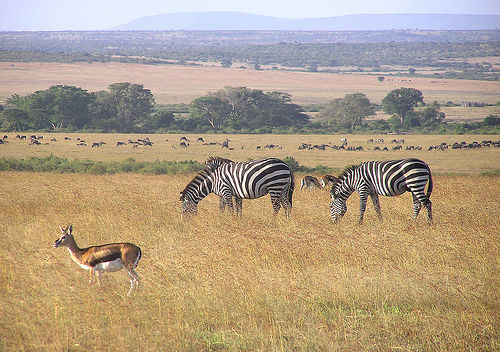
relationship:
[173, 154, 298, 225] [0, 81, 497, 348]
zebra in bush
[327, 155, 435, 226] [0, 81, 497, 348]
zebra in bush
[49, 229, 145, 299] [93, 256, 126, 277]
antelope with belly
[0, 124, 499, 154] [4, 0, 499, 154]
animals in distance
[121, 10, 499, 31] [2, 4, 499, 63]
mountain on horizon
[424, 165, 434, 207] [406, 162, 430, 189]
tail on back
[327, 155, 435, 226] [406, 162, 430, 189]
zebra has back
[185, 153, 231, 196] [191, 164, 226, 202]
mane on neck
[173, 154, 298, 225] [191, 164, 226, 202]
zebra has neck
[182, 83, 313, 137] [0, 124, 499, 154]
tree beyond herd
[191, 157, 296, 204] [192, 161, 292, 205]
stripes on torso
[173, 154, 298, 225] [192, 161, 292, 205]
zebra has torso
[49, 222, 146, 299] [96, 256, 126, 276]
antelope has belly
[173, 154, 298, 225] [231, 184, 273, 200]
zebra has stomach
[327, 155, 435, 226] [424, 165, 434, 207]
zebra has tail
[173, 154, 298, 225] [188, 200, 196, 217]
zebra has jaw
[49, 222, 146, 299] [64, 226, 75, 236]
antelope has ear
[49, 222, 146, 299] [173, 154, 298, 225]
antelope beside zebra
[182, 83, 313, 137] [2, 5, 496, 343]
tree in photo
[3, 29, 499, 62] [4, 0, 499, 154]
savannah in distance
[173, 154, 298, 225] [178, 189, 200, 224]
zebra has head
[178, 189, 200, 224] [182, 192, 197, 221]
head with stripes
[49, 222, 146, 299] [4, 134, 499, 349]
antelope on field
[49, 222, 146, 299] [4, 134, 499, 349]
antelope in field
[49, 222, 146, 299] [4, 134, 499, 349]
antelope standing in field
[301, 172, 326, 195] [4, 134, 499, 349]
deer in field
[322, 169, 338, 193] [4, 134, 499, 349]
deer in field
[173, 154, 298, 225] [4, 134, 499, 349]
animal in field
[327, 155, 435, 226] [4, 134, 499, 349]
animal in field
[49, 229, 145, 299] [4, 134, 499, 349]
animal in field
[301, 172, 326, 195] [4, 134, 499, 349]
animal in field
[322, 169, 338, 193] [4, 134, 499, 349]
animal in field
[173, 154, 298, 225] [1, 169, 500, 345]
zebra on grass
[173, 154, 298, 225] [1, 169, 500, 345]
zebra grazing on grass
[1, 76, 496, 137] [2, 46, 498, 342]
bushes dividing pasture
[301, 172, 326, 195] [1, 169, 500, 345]
deer eating grass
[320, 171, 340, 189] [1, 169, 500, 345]
animal eating grass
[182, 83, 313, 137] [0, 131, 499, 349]
tree in field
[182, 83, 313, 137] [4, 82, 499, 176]
tree in middle